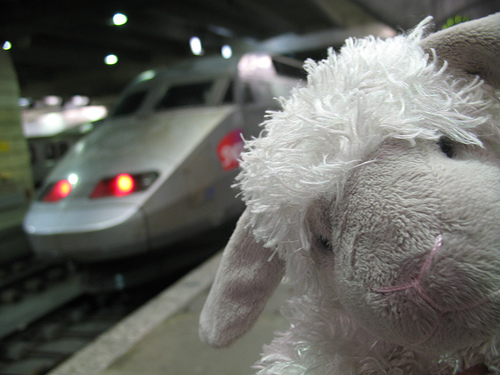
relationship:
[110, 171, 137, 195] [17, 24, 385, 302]
headlight on train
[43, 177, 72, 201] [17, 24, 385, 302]
headlight on train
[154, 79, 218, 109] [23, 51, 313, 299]
windscreen on train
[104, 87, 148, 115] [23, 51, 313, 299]
windscreen on train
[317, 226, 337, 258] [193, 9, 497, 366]
eye on teddy bear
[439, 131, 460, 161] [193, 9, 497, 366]
eye on teddy bear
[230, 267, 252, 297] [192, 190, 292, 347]
section of a ear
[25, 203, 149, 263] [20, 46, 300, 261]
front of a train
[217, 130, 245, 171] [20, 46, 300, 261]
logo on a train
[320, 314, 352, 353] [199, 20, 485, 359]
section of a teddybear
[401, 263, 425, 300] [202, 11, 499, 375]
nose of a toy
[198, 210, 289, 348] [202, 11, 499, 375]
ear of a toy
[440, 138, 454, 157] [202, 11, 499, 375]
eye of a toy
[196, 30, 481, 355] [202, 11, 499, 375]
head of a toy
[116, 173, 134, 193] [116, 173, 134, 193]
headlight of an headlight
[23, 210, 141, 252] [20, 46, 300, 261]
front of a train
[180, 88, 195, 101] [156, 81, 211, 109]
part of a windscreen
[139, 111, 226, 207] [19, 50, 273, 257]
edge of train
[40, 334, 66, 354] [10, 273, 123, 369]
part of a rail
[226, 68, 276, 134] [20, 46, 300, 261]
side of train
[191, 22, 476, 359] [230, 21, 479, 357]
toy has hair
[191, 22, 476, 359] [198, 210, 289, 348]
toy has ear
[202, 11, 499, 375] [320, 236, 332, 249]
toy has eye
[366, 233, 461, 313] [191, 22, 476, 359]
configuration in on toy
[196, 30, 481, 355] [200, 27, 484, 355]
head at an angle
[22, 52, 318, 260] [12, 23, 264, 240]
train in background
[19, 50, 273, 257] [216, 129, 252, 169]
train has a logo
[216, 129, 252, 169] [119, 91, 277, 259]
logo on side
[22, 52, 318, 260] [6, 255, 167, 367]
train on tracks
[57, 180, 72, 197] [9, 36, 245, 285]
headlight of train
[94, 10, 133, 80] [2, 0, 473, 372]
lights on in train station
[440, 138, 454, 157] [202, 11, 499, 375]
eye of toy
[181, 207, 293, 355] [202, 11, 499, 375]
ear of toy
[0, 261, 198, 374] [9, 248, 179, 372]
rail on ground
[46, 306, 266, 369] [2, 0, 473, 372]
platform at train station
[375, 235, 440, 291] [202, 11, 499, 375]
nose of toy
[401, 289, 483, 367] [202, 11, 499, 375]
mouth of toy